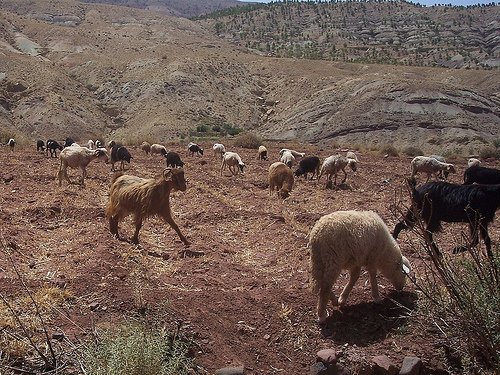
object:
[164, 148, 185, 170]
goat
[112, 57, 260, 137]
hill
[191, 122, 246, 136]
patch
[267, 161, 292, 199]
goats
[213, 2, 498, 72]
mountain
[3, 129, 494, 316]
sheep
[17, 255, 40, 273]
goat poop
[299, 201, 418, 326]
sheep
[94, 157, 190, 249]
goat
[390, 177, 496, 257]
goat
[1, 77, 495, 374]
hillside prarie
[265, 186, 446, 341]
sheep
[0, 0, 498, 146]
hills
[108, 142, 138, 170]
goat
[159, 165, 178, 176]
horns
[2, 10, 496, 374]
hill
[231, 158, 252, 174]
head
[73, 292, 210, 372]
bush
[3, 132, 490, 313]
herd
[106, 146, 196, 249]
sheep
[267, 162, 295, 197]
sheep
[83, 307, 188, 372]
shrub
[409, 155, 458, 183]
sheep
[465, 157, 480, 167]
sheep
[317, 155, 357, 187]
sheep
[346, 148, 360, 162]
sheep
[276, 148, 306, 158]
sheep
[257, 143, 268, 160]
sheep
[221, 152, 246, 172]
sheep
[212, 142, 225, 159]
sheep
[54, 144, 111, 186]
sheep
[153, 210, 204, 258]
foot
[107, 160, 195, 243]
goats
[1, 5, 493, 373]
mountain valley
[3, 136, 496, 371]
hill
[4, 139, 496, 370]
ground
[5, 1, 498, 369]
field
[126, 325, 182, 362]
plant